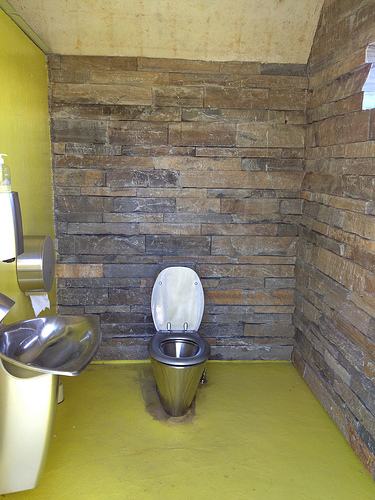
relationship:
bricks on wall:
[46, 52, 305, 361] [46, 54, 307, 360]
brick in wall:
[104, 166, 144, 185] [51, 58, 297, 340]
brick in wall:
[143, 234, 213, 251] [51, 58, 297, 340]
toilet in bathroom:
[145, 267, 207, 417] [1, 17, 373, 496]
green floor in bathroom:
[55, 361, 322, 498] [1, 17, 373, 496]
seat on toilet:
[153, 327, 208, 366] [148, 263, 211, 414]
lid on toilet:
[147, 264, 205, 331] [145, 267, 207, 417]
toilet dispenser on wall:
[21, 234, 53, 308] [1, 16, 60, 339]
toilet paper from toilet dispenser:
[26, 292, 48, 312] [15, 234, 54, 297]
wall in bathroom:
[304, 3, 373, 422] [1, 17, 373, 496]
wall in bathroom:
[51, 58, 297, 340] [1, 17, 373, 496]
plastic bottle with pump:
[1, 155, 8, 184] [0, 151, 7, 168]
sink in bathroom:
[2, 317, 96, 370] [1, 17, 373, 496]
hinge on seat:
[180, 322, 190, 332] [146, 329, 212, 366]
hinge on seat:
[164, 320, 172, 331] [146, 329, 212, 366]